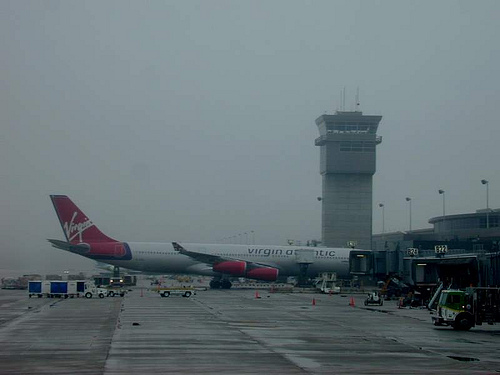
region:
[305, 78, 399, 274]
Concrete airplane control tower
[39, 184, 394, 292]
Airplane parked at terminal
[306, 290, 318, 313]
Small orange safety cone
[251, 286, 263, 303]
Small orange safety cone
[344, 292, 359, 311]
Small orange safety cone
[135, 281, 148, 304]
Small orange safety cone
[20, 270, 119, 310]
Large white cargo truck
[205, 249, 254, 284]
Airplane engine painted red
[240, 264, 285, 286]
Airplane engine painted red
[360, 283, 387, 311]
Small airport vehicle next to airplane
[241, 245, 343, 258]
Sign on side of plane for virgin airlines.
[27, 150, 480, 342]
An air plane at the hangar.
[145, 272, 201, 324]
Red tail of plane.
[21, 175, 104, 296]
Red tail of plane that says virgin .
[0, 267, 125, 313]
Blue and white semi truck.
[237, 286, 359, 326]
Cement with orange traffic cones.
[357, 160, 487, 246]
Four lights on building.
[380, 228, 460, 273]
Two sets of numbers on building.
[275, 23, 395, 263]
The watch tower at an airport.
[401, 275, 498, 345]
A garbage truck.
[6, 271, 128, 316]
This is a blue truck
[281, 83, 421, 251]
This is a silver watch tower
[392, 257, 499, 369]
This is a white truck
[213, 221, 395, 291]
This plane belongs to virgin Atlantic.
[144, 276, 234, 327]
This is a yellow truck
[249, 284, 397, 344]
There are traffic cones.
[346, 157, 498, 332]
There are a lot of street lights.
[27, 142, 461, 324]
This plane is white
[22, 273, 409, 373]
This is a cement floor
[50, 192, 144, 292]
this color is red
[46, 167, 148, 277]
Red tail of a plane.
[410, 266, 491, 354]
Green and white garbage truck.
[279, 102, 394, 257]
Tall watch tower at air port.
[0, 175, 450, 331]
A virgin atlantic plane at air port.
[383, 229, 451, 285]
Two black and white number boards.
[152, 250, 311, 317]
Red engine on wing.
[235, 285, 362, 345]
Orange traffic cones on cement.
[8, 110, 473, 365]
A plane at an airport.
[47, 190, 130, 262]
the plane's tail is painted red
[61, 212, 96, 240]
the plane has lettering on it's tail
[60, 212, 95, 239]
the lettering is white in color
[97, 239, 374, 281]
the plane is painted white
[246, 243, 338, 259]
the plane has lettering on the side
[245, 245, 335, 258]
the lettering is black in color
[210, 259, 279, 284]
the plane has two engines on it's wing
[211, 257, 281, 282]
the engines are red in color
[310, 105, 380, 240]
the tower is grey in color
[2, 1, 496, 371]
the day is overcast